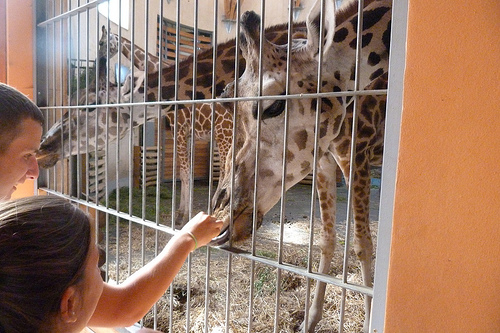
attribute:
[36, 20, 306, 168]
giraffe — being fed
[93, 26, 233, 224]
giraffe — being fed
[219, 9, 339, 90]
horns — brown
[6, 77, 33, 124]
hair — brown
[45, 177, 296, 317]
arm — human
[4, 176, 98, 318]
hair — brown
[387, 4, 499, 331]
wall — orange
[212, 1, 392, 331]
giraffe — being fed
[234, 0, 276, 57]
antler — long